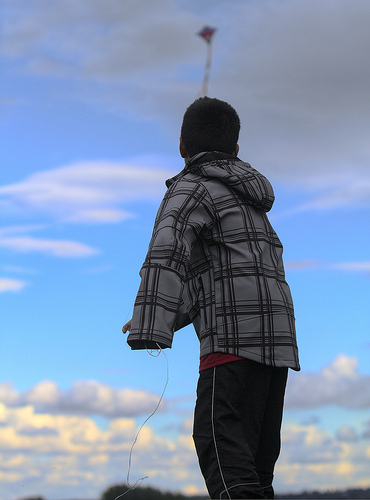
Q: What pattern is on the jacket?
A: Plaid.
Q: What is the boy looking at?
A: Kite.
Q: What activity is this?
A: Kite flying.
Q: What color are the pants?
A: Black.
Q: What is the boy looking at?
A: Kite.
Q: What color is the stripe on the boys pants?
A: White.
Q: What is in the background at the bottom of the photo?
A: Trees.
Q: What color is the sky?
A: Turquoise.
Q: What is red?
A: Bottom of boys shirt.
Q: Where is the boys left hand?
A: Up his sleeve.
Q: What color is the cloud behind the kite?
A: Grey.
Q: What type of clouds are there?
A: Cumulus.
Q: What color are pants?
A: Black with white line.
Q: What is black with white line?
A: Pants.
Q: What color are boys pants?
A: Black with a white line.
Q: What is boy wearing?
A: Black pants with white stripe.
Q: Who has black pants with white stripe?
A: The boy.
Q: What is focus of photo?
A: Pants that are black and have white stripe.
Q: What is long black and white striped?
A: Pants.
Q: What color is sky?
A: Blue and white.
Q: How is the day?
A: Sky is blue and white.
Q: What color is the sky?
A: Blue.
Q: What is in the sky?
A: A kite.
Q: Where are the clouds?
A: Above the kite.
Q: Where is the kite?
A: In the sky.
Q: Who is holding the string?
A: The boy.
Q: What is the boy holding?
A: The string.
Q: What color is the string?
A: White.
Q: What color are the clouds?
A: Gray and white.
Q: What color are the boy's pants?
A: Black.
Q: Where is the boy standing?
A: On the ground under the kite.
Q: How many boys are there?
A: One.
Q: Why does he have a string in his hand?
A: To control the kite.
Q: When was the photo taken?
A: During the day.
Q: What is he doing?
A: Flying a kite.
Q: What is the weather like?
A: Sunny with a few clouds.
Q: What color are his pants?
A: Black.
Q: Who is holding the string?
A: The boy.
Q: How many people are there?
A: One.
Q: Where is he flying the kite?
A: At a park.